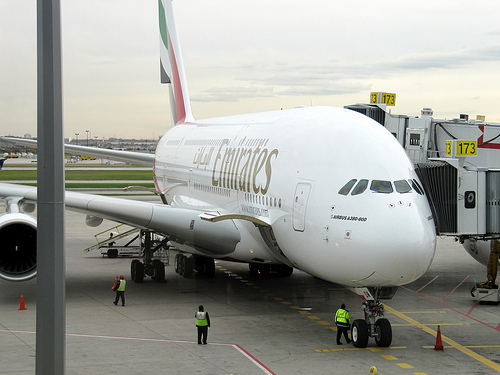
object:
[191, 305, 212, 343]
people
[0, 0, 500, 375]
outdoors